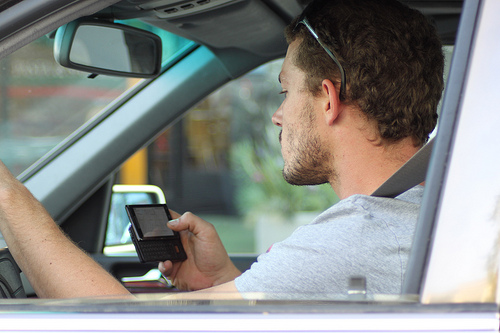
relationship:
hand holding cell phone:
[156, 205, 231, 292] [126, 203, 188, 263]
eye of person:
[268, 58, 315, 125] [241, 12, 433, 329]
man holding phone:
[0, 0, 446, 301] [124, 199, 187, 264]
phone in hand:
[125, 201, 188, 270] [156, 205, 231, 292]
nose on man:
[268, 96, 286, 126] [0, 0, 446, 301]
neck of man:
[325, 139, 429, 206] [0, 0, 446, 301]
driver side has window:
[2, 3, 472, 330] [18, 17, 436, 309]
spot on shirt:
[354, 205, 390, 227] [231, 185, 424, 295]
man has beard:
[0, 0, 446, 301] [273, 110, 376, 190]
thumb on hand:
[163, 208, 215, 235] [161, 209, 231, 293]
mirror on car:
[48, 28, 173, 77] [2, 3, 498, 331]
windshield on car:
[0, 19, 202, 179] [2, 3, 498, 331]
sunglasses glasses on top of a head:
[287, 5, 350, 101] [250, 19, 459, 253]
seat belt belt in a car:
[370, 135, 435, 197] [24, 192, 492, 293]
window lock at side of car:
[348, 276, 366, 303] [0, 147, 498, 323]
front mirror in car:
[59, 50, 149, 105] [19, 187, 498, 333]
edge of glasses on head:
[337, 75, 359, 105] [270, 3, 446, 186]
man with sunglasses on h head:
[0, 0, 446, 301] [298, 106, 373, 210]